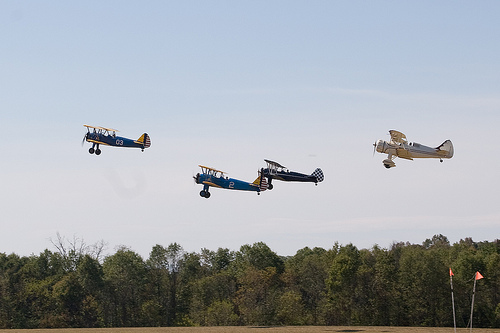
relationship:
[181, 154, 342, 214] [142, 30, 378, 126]
airplanes are in sky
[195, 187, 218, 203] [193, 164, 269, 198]
tire on airplanes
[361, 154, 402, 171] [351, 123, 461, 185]
tire on plane